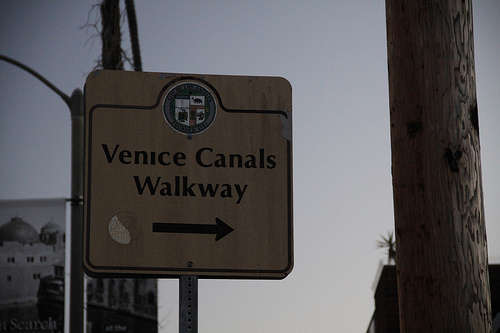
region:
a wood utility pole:
[373, 2, 496, 325]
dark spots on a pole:
[381, 88, 490, 182]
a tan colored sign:
[76, 67, 309, 284]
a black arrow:
[141, 210, 248, 260]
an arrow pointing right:
[141, 196, 259, 241]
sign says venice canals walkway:
[74, 59, 314, 298]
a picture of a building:
[4, 181, 154, 326]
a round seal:
[154, 72, 233, 139]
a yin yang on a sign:
[94, 197, 152, 260]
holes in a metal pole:
[172, 253, 209, 331]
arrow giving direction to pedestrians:
[128, 210, 246, 250]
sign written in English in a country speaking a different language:
[95, 130, 280, 205]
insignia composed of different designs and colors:
[155, 72, 220, 137]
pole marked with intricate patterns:
[370, 25, 492, 305]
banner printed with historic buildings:
[7, 185, 64, 325]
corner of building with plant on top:
[340, 222, 457, 322]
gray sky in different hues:
[302, 15, 372, 255]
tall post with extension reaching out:
[5, 36, 80, 252]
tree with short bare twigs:
[65, 7, 130, 59]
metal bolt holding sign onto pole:
[165, 250, 215, 292]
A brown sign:
[80, 68, 303, 291]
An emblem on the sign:
[159, 80, 225, 140]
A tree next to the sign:
[370, 2, 496, 331]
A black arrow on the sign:
[139, 209, 247, 250]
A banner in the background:
[1, 186, 76, 330]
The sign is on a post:
[84, 64, 309, 331]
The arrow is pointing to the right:
[119, 207, 267, 258]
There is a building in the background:
[346, 240, 498, 331]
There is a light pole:
[1, 47, 111, 331]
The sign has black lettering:
[78, 66, 301, 306]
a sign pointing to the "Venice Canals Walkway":
[85, 55, 312, 295]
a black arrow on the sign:
[146, 210, 244, 247]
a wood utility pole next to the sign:
[373, 23, 493, 233]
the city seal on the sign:
[156, 79, 217, 140]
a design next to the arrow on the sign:
[96, 201, 151, 254]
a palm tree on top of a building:
[371, 227, 405, 267]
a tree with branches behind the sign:
[84, 4, 142, 79]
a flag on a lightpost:
[11, 194, 78, 321]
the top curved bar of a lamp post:
[5, 48, 83, 135]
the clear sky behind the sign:
[301, 30, 378, 180]